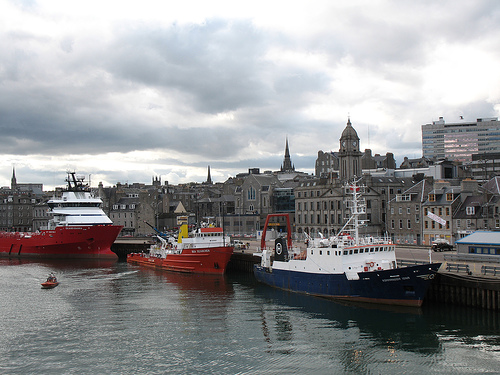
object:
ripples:
[64, 313, 234, 373]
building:
[235, 173, 300, 232]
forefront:
[4, 258, 499, 371]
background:
[272, 131, 302, 174]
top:
[339, 111, 361, 152]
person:
[47, 272, 58, 283]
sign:
[427, 211, 446, 225]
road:
[220, 237, 498, 274]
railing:
[443, 255, 500, 264]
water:
[0, 300, 408, 372]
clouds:
[314, 3, 496, 93]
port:
[0, 167, 500, 304]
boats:
[128, 227, 236, 276]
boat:
[253, 175, 441, 308]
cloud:
[5, 40, 137, 159]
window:
[264, 198, 266, 207]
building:
[422, 115, 498, 177]